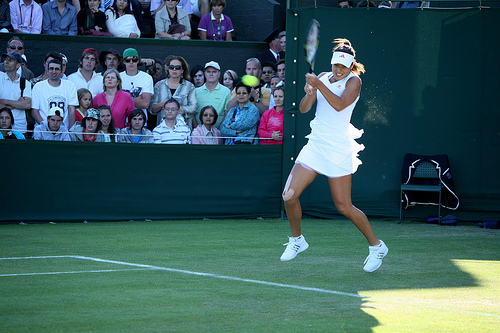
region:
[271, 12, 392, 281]
The woman is holding a tennis racket.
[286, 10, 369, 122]
The woman is wearing a vidor.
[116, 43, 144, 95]
The man is wearing sunglasses.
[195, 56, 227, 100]
The man is wearing a cap.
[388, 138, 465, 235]
The chair is empty.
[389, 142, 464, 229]
Jacket hanging on back of chair.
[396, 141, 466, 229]
The jacket is blue and white.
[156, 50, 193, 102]
The woman is wearing sunglasses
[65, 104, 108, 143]
The man is wearing a cap.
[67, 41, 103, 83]
The man is wearing a cap.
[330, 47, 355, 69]
White visor with red symbol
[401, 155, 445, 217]
Blue chair by the wall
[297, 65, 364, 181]
White tennis dress with red symbol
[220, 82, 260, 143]
Woman in blue shirt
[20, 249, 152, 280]
White lines on tennis court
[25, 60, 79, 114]
Man in white t-shirt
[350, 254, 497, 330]
Sunlight reflecting off of the ground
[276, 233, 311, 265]
White tennis show with white shoestrings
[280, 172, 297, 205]
Bandage on right knee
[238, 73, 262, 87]
Yellow tennis ball in the air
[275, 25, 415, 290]
woman wearing a visor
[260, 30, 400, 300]
woman wearing a t shirt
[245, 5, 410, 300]
woman wearing white skirt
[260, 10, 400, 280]
woman wearing a white tennis shoes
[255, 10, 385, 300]
woman holding a racket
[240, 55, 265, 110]
ball in the air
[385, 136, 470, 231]
chair next to fence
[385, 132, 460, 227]
jacket on a chair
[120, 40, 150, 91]
woman wearing a cap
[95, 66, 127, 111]
woman wearing pink shirt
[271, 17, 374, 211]
the player is holding a racket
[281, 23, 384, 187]
the player is holding a racket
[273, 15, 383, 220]
the player is holding a racket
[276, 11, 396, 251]
the player is holding a racket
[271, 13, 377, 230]
the player is holding a racket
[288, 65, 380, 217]
the dress is white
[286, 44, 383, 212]
the dress is white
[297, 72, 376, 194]
the dress is white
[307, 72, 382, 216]
the dress is white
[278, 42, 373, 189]
the dress is white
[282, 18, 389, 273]
a female tennis player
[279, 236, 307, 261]
a white tennis shoe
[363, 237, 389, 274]
a white tennis shoe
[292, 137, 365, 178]
a white tennis skirt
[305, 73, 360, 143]
a white tennis top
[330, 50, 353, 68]
a women's white visor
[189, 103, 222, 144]
a woman sitting in stands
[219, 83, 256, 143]
a woman sitting in stands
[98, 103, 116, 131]
a woman sitting in stands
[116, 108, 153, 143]
a man sitting in stands